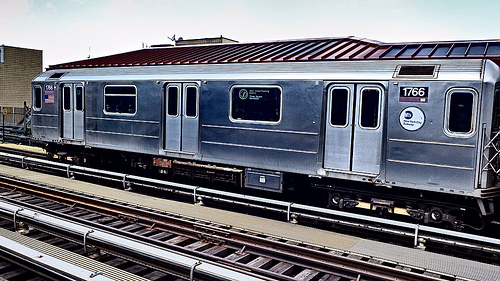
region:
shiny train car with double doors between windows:
[27, 60, 494, 210]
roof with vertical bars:
[37, 38, 495, 68]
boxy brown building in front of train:
[1, 45, 43, 110]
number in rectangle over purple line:
[397, 85, 427, 102]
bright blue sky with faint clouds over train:
[5, 3, 496, 59]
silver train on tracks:
[59, 56, 478, 189]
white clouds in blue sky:
[25, 4, 74, 37]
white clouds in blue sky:
[49, 14, 72, 42]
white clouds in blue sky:
[149, 12, 185, 33]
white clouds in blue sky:
[284, 4, 329, 23]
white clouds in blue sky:
[339, 4, 366, 26]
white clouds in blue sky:
[419, 7, 448, 33]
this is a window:
[354, 84, 386, 129]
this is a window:
[323, 85, 351, 130]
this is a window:
[226, 80, 296, 135]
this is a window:
[182, 88, 207, 120]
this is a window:
[162, 87, 184, 119]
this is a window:
[102, 86, 137, 118]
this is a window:
[61, 84, 82, 109]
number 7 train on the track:
[236, 81, 256, 102]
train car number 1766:
[393, 79, 442, 107]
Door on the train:
[316, 72, 383, 194]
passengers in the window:
[99, 98, 137, 115]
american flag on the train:
[42, 90, 55, 102]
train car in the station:
[14, 55, 498, 209]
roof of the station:
[58, 20, 498, 70]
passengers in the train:
[213, 88, 292, 118]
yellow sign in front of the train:
[2, 103, 10, 115]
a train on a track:
[49, 42, 290, 256]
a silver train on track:
[72, 34, 269, 187]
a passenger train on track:
[77, 50, 499, 225]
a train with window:
[454, 93, 491, 138]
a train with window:
[33, 83, 47, 110]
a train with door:
[60, 83, 85, 145]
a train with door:
[164, 85, 199, 156]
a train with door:
[332, 81, 390, 178]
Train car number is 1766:
[398, 84, 430, 99]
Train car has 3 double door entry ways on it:
[26, 62, 497, 218]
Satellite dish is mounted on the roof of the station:
[167, 33, 179, 43]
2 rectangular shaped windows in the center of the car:
[92, 80, 299, 130]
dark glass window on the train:
[73, 85, 79, 110]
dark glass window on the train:
[103, 93, 135, 113]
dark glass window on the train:
[105, 83, 135, 91]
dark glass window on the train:
[166, 85, 176, 115]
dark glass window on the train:
[185, 82, 195, 117]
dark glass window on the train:
[231, 85, 279, 120]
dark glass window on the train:
[330, 87, 346, 122]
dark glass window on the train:
[362, 89, 377, 129]